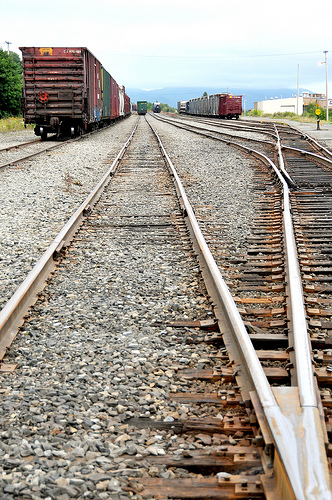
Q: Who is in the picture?
A: No one.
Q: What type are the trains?
A: Cargo train.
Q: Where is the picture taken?
A: Railroad track.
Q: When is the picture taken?
A: During the day.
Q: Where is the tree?
A: Upper left corner.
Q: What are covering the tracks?
A: Rocks.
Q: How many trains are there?
A: Four.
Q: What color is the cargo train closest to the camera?
A: Red.